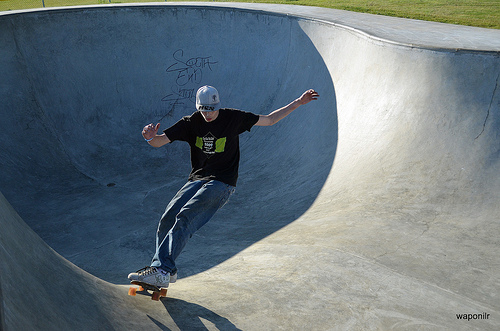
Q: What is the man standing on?
A: Skateboard.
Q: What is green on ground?
A: Grass.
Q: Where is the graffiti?
A: Wall behind skater.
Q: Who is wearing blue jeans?
A: Skateboarder.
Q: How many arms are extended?
A: 2.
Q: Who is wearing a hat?
A: Skateboarder.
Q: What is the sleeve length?
A: Short.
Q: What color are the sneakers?
A: White.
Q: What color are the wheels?
A: Orange.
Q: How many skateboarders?
A: 1.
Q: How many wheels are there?
A: 4.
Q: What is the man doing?
A: Skateboarding.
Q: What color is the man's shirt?
A: Black.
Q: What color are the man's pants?
A: Blue.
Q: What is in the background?
A: Grass.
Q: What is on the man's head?
A: Hat.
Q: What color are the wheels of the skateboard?
A: Orange.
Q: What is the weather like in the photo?
A: Sunny.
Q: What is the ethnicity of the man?
A: Caucasian.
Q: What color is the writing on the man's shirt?
A: Green.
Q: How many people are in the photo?
A: One.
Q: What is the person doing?
A: Skateboarding.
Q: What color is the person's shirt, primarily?
A: Black.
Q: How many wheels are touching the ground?
A: Two.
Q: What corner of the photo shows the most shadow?
A: Top left.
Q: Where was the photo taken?
A: Park.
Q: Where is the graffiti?
A: Behind the skateboarder's head.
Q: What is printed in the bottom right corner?
A: Waponilr.